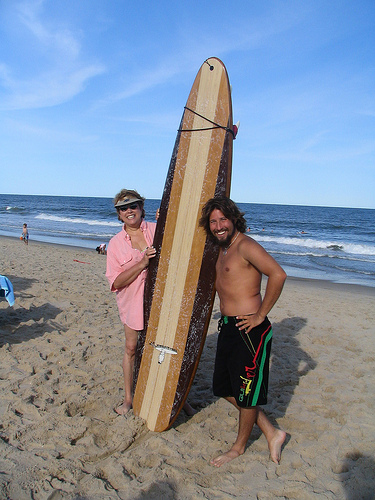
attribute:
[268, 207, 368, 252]
ocean — blue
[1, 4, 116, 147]
clouds — white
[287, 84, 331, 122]
sky — blue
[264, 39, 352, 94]
clouds — white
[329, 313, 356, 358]
sand — tan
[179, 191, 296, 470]
man — barefoot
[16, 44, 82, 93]
clouds — white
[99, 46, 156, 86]
sky — blue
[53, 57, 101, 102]
clouds — white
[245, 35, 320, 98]
sky — blue